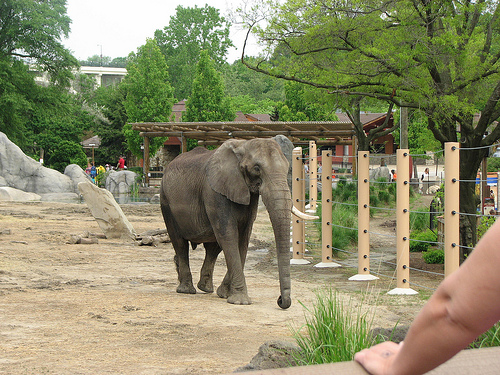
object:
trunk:
[265, 177, 299, 311]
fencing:
[288, 139, 499, 297]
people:
[113, 153, 128, 171]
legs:
[213, 219, 256, 306]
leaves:
[439, 115, 450, 124]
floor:
[0, 201, 393, 374]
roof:
[129, 117, 374, 141]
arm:
[391, 215, 499, 372]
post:
[345, 148, 379, 284]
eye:
[247, 163, 265, 175]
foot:
[222, 285, 256, 306]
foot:
[174, 276, 195, 294]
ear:
[203, 150, 252, 206]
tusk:
[288, 205, 321, 224]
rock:
[75, 181, 134, 242]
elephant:
[159, 134, 322, 308]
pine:
[120, 38, 171, 178]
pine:
[180, 55, 236, 151]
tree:
[239, 0, 499, 269]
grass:
[279, 288, 386, 366]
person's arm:
[388, 215, 499, 375]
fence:
[231, 345, 499, 374]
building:
[21, 60, 164, 130]